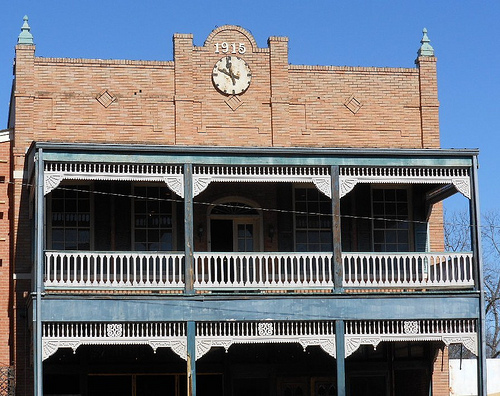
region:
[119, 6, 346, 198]
a clock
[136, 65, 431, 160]
a clock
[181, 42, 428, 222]
a clock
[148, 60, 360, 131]
a clock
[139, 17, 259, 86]
a clock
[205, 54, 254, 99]
an antique public clock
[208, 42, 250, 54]
the number 1915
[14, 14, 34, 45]
a green patina finial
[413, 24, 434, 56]
a green patina finial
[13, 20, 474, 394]
an old brick building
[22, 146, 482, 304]
an outdoor shaded balcony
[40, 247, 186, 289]
a stretch of white wood railing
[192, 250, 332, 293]
a stretch of white wood railing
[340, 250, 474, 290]
a stretch of white wood railing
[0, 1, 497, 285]
a deep blue sky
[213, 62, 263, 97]
A clock on the building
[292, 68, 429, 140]
a brown building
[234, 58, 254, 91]
numbers on the clock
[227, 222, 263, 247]
The door of the building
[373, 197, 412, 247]
Windows of the building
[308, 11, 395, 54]
The clear blue sky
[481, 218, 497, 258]
Tree branches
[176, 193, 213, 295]
Blue poles on the house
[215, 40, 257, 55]
The numbers on the building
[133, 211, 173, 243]
Windows on the building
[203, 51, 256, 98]
big old analog clock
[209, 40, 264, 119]
big old analog clock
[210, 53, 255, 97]
a white clock face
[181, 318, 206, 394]
a blue wooden board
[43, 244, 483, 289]
a white railing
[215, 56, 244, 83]
the hands of a clock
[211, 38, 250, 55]
numbers on the building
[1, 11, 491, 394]
a brick and wood building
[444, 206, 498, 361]
a barren tree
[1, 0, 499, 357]
a clear blue sky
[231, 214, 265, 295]
a door on the building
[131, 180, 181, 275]
a window on the building